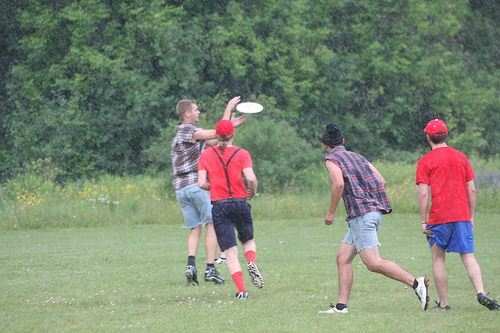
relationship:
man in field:
[170, 95, 264, 286] [22, 214, 133, 292]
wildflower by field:
[23, 160, 151, 222] [22, 214, 133, 292]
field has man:
[22, 214, 133, 292] [210, 112, 282, 278]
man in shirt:
[210, 112, 282, 278] [322, 136, 386, 236]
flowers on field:
[13, 176, 128, 226] [22, 214, 133, 292]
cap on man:
[208, 106, 236, 139] [210, 112, 282, 278]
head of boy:
[319, 120, 353, 151] [309, 117, 434, 324]